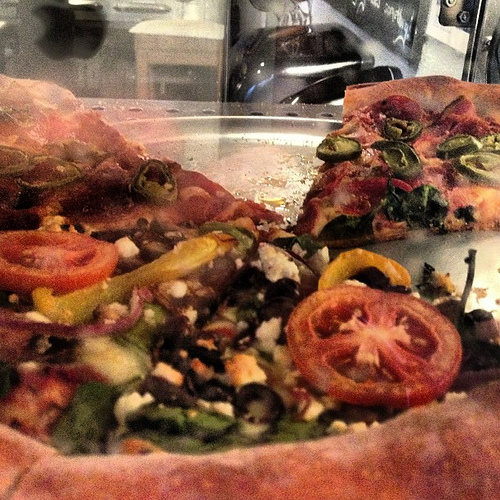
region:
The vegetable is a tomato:
[299, 295, 434, 401]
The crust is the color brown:
[86, 440, 466, 498]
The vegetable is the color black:
[232, 379, 288, 426]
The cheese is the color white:
[260, 247, 298, 279]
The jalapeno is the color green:
[314, 133, 363, 164]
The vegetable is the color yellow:
[321, 244, 406, 287]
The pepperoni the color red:
[308, 162, 360, 198]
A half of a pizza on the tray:
[3, 129, 493, 499]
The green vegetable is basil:
[336, 180, 466, 228]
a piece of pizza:
[286, 67, 496, 242]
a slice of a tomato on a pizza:
[281, 276, 471, 413]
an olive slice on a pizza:
[228, 377, 287, 427]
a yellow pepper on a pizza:
[319, 242, 410, 291]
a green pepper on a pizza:
[129, 398, 225, 435]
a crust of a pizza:
[99, 437, 351, 498]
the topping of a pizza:
[109, 232, 251, 382]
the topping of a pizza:
[349, 125, 487, 203]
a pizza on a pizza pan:
[30, 85, 440, 221]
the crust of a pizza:
[339, 70, 481, 103]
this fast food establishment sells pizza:
[2, 69, 498, 497]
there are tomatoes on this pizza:
[279, 280, 465, 405]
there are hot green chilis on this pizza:
[309, 115, 499, 185]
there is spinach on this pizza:
[315, 180, 452, 247]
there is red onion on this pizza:
[0, 278, 150, 344]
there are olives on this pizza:
[226, 377, 289, 429]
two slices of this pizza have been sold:
[2, 71, 499, 498]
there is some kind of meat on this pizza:
[361, 90, 491, 145]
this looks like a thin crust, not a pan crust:
[334, 70, 499, 132]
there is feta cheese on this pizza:
[253, 238, 305, 286]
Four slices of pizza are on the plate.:
[0, 85, 499, 498]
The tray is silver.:
[110, 113, 498, 309]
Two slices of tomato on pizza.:
[2, 223, 463, 399]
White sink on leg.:
[128, 18, 221, 99]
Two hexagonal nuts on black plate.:
[439, 0, 478, 35]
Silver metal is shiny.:
[231, 22, 360, 119]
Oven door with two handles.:
[66, 0, 229, 20]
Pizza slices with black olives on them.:
[5, 120, 496, 437]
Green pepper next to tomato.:
[31, 230, 238, 332]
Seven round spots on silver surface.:
[88, 102, 338, 121]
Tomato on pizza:
[291, 251, 401, 397]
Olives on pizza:
[175, 311, 277, 428]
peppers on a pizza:
[63, 230, 218, 357]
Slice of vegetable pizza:
[283, 45, 415, 275]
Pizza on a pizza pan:
[105, 128, 383, 400]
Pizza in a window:
[74, 72, 369, 359]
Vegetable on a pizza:
[41, 108, 269, 365]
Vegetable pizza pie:
[124, 136, 379, 398]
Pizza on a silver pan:
[119, 105, 448, 373]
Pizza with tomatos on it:
[188, 178, 488, 480]